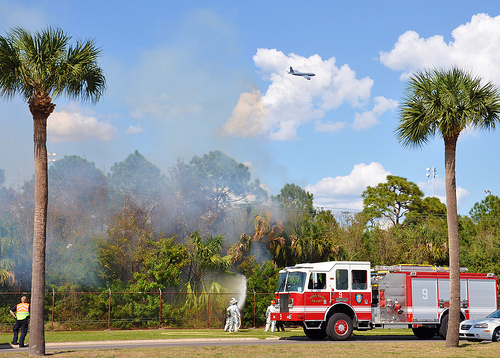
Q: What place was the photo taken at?
A: It was taken at the forest.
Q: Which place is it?
A: It is a forest.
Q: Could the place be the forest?
A: Yes, it is the forest.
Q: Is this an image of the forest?
A: Yes, it is showing the forest.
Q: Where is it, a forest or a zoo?
A: It is a forest.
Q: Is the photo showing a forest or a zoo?
A: It is showing a forest.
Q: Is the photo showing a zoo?
A: No, the picture is showing a forest.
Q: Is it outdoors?
A: Yes, it is outdoors.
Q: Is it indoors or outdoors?
A: It is outdoors.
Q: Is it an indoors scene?
A: No, it is outdoors.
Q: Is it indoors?
A: No, it is outdoors.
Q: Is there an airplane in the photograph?
A: Yes, there is an airplane.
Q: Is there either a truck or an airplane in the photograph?
A: Yes, there is an airplane.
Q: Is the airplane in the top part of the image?
A: Yes, the airplane is in the top of the image.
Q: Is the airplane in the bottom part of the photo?
A: No, the airplane is in the top of the image.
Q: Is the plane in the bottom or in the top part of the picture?
A: The plane is in the top of the image.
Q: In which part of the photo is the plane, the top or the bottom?
A: The plane is in the top of the image.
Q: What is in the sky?
A: The plane is in the sky.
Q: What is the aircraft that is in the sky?
A: The aircraft is an airplane.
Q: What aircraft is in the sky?
A: The aircraft is an airplane.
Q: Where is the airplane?
A: The airplane is in the sky.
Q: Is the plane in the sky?
A: Yes, the plane is in the sky.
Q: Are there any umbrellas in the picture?
A: No, there are no umbrellas.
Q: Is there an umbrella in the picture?
A: No, there are no umbrellas.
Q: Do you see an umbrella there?
A: No, there are no umbrellas.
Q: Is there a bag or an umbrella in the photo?
A: No, there are no umbrellas or bags.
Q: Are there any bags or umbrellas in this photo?
A: No, there are no umbrellas or bags.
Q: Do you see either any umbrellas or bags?
A: No, there are no umbrellas or bags.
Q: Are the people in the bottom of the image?
A: Yes, the people are in the bottom of the image.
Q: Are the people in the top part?
A: No, the people are in the bottom of the image.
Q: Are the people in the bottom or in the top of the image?
A: The people are in the bottom of the image.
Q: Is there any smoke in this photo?
A: Yes, there is smoke.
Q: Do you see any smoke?
A: Yes, there is smoke.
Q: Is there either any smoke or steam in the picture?
A: Yes, there is smoke.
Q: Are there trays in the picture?
A: No, there are no trays.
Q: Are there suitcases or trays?
A: No, there are no trays or suitcases.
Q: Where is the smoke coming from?
A: The smoke is coming from the trees.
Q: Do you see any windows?
A: Yes, there is a window.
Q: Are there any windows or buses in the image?
A: Yes, there is a window.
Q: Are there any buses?
A: No, there are no buses.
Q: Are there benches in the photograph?
A: No, there are no benches.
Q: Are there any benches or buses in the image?
A: No, there are no benches or buses.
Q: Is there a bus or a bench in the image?
A: No, there are no benches or buses.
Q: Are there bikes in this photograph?
A: No, there are no bikes.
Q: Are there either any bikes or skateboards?
A: No, there are no bikes or skateboards.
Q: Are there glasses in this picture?
A: No, there are no glasses.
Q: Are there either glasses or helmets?
A: No, there are no glasses or helmets.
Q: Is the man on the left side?
A: Yes, the man is on the left of the image.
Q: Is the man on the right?
A: No, the man is on the left of the image.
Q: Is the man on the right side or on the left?
A: The man is on the left of the image.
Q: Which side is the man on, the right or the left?
A: The man is on the left of the image.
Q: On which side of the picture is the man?
A: The man is on the left of the image.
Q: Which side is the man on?
A: The man is on the left of the image.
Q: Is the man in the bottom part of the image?
A: Yes, the man is in the bottom of the image.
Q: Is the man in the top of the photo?
A: No, the man is in the bottom of the image.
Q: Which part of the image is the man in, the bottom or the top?
A: The man is in the bottom of the image.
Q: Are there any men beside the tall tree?
A: Yes, there is a man beside the tree.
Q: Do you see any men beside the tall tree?
A: Yes, there is a man beside the tree.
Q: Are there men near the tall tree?
A: Yes, there is a man near the tree.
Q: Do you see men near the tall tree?
A: Yes, there is a man near the tree.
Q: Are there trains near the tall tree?
A: No, there is a man near the tree.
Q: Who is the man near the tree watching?
A: The man is watching the people.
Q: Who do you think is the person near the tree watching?
A: The man is watching the people.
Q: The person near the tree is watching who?
A: The man is watching the people.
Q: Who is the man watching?
A: The man is watching the people.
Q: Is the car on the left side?
A: No, the car is on the right of the image.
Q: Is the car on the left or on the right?
A: The car is on the right of the image.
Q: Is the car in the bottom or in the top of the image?
A: The car is in the bottom of the image.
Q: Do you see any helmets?
A: No, there are no helmets.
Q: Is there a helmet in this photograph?
A: No, there are no helmets.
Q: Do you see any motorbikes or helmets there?
A: No, there are no helmets or motorbikes.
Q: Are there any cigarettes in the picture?
A: No, there are no cigarettes.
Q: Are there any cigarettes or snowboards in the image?
A: No, there are no cigarettes or snowboards.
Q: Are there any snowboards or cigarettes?
A: No, there are no cigarettes or snowboards.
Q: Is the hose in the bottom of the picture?
A: Yes, the hose is in the bottom of the image.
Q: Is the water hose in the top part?
A: No, the water hose is in the bottom of the image.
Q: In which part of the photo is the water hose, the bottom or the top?
A: The water hose is in the bottom of the image.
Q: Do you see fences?
A: Yes, there is a fence.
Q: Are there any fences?
A: Yes, there is a fence.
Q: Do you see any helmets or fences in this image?
A: Yes, there is a fence.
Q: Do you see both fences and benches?
A: No, there is a fence but no benches.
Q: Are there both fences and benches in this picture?
A: No, there is a fence but no benches.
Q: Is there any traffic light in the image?
A: No, there are no traffic lights.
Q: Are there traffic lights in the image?
A: No, there are no traffic lights.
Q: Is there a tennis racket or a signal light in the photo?
A: No, there are no traffic lights or rackets.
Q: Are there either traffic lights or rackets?
A: No, there are no traffic lights or rackets.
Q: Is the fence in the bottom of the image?
A: Yes, the fence is in the bottom of the image.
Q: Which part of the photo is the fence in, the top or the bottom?
A: The fence is in the bottom of the image.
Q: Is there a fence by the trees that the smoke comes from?
A: Yes, there is a fence by the trees.